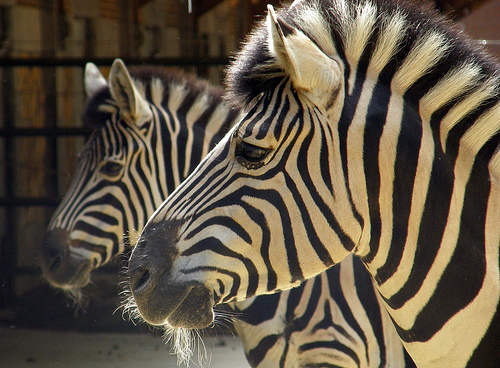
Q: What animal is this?
A: Zebra.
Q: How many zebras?
A: Two.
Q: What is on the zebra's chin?
A: Whiskers.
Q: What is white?
A: Ears.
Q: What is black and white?
A: Zebras.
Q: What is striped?
A: Zebras.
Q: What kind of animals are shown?
A: Zebras.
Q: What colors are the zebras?
A: Black and white.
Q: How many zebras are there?
A: 2.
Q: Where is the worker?
A: Not in the photo.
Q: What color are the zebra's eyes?
A: Black.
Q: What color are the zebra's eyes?
A: Black.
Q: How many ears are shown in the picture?
A: 3.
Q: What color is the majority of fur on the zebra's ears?
A: White.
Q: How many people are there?
A: 0.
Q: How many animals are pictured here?
A: Two.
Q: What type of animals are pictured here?
A: Zebras.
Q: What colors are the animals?
A: Black and white.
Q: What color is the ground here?
A: Grey.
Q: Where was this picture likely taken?
A: A zoo.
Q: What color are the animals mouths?
A: Black.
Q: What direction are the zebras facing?
A: Left.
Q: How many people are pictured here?
A: Zero.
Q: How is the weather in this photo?
A: Sunny.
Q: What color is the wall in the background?
A: Tan.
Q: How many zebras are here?
A: 2.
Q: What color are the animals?
A: Black and white.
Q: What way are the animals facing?
A: Left.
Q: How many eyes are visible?
A: Two.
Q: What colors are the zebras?
A: Black and white.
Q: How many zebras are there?
A: Two.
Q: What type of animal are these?
A: Zebras.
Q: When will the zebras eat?
A: When they get hungry.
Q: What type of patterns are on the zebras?
A: Stripes.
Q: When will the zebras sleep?
A: When they are tired.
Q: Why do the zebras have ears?
A: To hear.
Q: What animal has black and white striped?
A: Zebras.